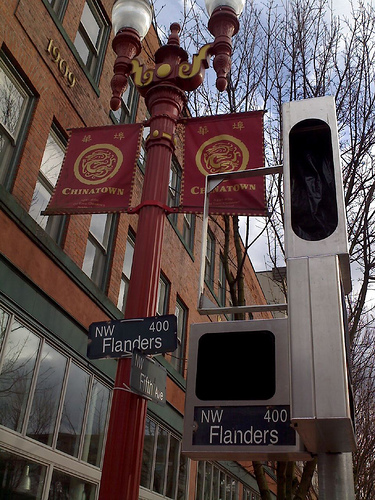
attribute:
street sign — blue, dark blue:
[87, 314, 178, 361]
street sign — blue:
[128, 348, 166, 405]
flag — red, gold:
[172, 110, 273, 217]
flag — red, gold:
[40, 122, 143, 216]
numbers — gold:
[45, 36, 76, 88]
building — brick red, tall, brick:
[1, 1, 318, 500]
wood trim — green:
[1, 0, 318, 499]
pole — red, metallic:
[99, 4, 239, 499]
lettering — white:
[95, 325, 162, 352]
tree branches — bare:
[141, 0, 374, 499]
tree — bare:
[143, 0, 374, 499]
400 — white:
[149, 320, 170, 333]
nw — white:
[94, 325, 115, 337]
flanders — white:
[102, 337, 162, 353]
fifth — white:
[140, 371, 155, 395]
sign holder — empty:
[196, 164, 287, 316]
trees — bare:
[142, 1, 375, 500]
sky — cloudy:
[150, 0, 374, 499]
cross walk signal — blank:
[196, 331, 277, 399]